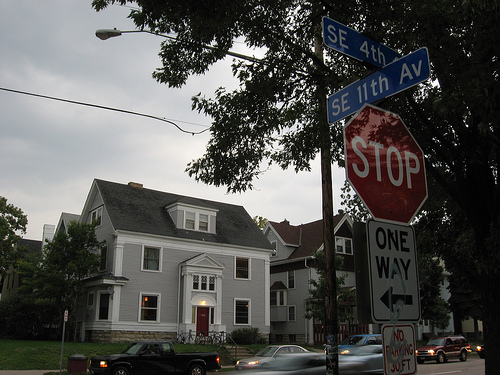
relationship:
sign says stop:
[339, 100, 435, 230] [350, 133, 422, 194]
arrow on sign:
[380, 285, 418, 314] [363, 217, 424, 324]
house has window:
[74, 175, 278, 362] [182, 207, 197, 232]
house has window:
[74, 175, 278, 362] [198, 211, 210, 234]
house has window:
[74, 175, 278, 362] [141, 243, 164, 275]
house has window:
[74, 175, 278, 362] [233, 253, 253, 282]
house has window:
[74, 175, 278, 362] [138, 292, 160, 322]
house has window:
[74, 175, 278, 362] [231, 297, 254, 324]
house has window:
[74, 175, 278, 362] [96, 292, 112, 323]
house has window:
[74, 175, 278, 362] [97, 244, 110, 272]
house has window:
[74, 175, 278, 362] [89, 205, 106, 229]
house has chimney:
[74, 175, 278, 362] [126, 180, 149, 192]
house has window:
[74, 175, 278, 362] [84, 291, 99, 310]